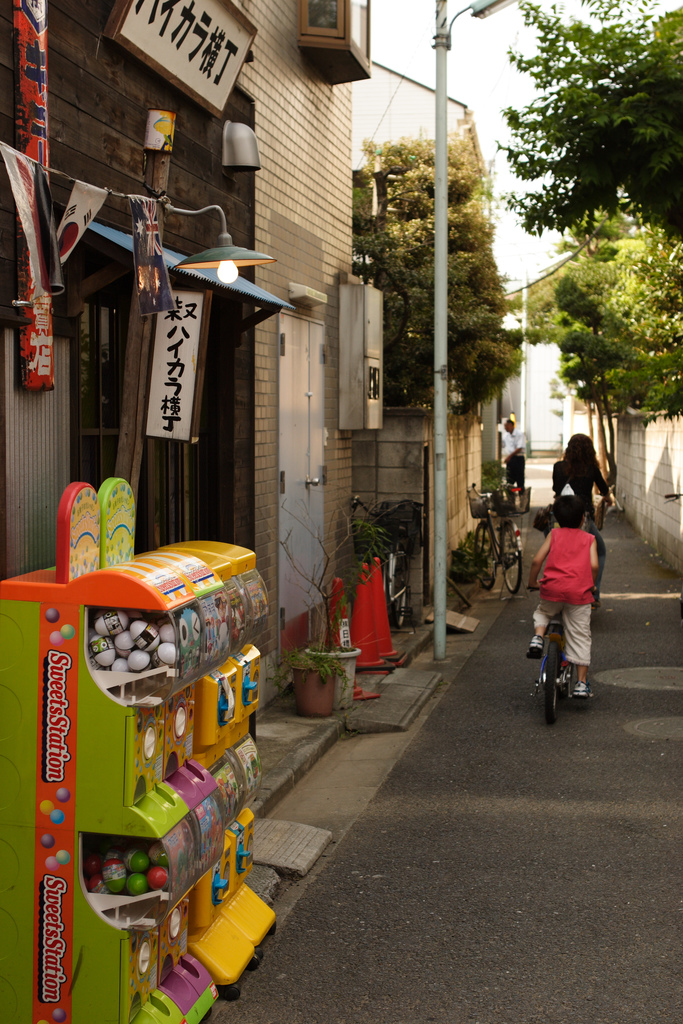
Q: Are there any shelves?
A: No, there are no shelves.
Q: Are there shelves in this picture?
A: No, there are no shelves.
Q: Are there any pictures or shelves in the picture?
A: No, there are no shelves or pictures.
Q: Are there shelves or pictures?
A: No, there are no shelves or pictures.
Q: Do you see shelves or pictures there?
A: No, there are no shelves or pictures.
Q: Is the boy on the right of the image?
A: Yes, the boy is on the right of the image.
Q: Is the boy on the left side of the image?
A: No, the boy is on the right of the image.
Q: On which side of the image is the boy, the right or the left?
A: The boy is on the right of the image.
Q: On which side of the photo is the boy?
A: The boy is on the right of the image.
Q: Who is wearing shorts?
A: The boy is wearing shorts.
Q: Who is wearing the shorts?
A: The boy is wearing shorts.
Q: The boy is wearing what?
A: The boy is wearing shorts.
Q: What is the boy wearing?
A: The boy is wearing shorts.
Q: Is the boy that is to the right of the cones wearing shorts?
A: Yes, the boy is wearing shorts.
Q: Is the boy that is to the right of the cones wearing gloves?
A: No, the boy is wearing shorts.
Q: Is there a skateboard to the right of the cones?
A: No, there is a boy to the right of the cones.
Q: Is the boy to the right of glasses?
A: No, the boy is to the right of the cones.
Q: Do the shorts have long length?
A: Yes, the shorts are long.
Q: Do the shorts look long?
A: Yes, the shorts are long.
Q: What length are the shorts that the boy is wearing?
A: The shorts are long.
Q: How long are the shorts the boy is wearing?
A: The shorts are long.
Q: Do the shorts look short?
A: No, the shorts are long.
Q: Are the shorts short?
A: No, the shorts are long.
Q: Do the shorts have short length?
A: No, the shorts are long.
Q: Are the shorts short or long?
A: The shorts are long.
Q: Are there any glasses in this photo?
A: No, there are no glasses.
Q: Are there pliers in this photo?
A: No, there are no pliers.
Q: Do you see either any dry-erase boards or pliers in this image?
A: No, there are no pliers or dry-erase boards.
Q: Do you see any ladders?
A: No, there are no ladders.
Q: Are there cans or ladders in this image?
A: No, there are no ladders or cans.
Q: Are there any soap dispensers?
A: No, there are no soap dispensers.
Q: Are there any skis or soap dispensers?
A: No, there are no soap dispensers or skis.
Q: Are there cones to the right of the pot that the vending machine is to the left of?
A: Yes, there are cones to the right of the pot.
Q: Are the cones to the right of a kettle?
A: No, the cones are to the right of a pot.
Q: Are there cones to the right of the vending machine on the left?
A: Yes, there are cones to the right of the vending machine.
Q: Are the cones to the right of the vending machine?
A: Yes, the cones are to the right of the vending machine.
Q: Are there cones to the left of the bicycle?
A: Yes, there are cones to the left of the bicycle.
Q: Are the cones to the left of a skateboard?
A: No, the cones are to the left of the bicycle.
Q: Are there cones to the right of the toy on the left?
A: Yes, there are cones to the right of the toy.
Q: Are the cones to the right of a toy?
A: Yes, the cones are to the right of a toy.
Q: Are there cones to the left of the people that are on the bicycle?
A: Yes, there are cones to the left of the people.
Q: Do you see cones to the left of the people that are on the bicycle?
A: Yes, there are cones to the left of the people.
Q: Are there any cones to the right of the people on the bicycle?
A: No, the cones are to the left of the people.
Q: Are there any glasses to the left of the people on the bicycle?
A: No, there are cones to the left of the people.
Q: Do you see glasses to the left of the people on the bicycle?
A: No, there are cones to the left of the people.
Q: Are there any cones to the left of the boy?
A: Yes, there are cones to the left of the boy.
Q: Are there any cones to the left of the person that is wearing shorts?
A: Yes, there are cones to the left of the boy.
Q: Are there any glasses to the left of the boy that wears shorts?
A: No, there are cones to the left of the boy.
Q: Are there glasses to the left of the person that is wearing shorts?
A: No, there are cones to the left of the boy.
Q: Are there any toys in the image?
A: Yes, there is a toy.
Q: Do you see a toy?
A: Yes, there is a toy.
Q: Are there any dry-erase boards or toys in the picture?
A: Yes, there is a toy.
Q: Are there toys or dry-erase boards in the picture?
A: Yes, there is a toy.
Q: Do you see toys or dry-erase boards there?
A: Yes, there is a toy.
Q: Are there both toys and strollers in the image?
A: No, there is a toy but no strollers.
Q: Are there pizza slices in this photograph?
A: No, there are no pizza slices.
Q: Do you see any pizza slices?
A: No, there are no pizza slices.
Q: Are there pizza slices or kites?
A: No, there are no pizza slices or kites.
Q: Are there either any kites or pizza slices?
A: No, there are no pizza slices or kites.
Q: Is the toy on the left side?
A: Yes, the toy is on the left of the image.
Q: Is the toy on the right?
A: No, the toy is on the left of the image.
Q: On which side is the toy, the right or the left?
A: The toy is on the left of the image.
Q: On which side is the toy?
A: The toy is on the left of the image.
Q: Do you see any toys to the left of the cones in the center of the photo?
A: Yes, there is a toy to the left of the cones.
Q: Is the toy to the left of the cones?
A: Yes, the toy is to the left of the cones.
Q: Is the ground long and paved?
A: Yes, the ground is long and paved.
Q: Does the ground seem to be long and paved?
A: Yes, the ground is long and paved.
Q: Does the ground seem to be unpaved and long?
A: No, the ground is long but paved.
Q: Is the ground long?
A: Yes, the ground is long.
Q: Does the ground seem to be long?
A: Yes, the ground is long.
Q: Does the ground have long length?
A: Yes, the ground is long.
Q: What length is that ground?
A: The ground is long.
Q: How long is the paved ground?
A: The ground is long.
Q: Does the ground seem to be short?
A: No, the ground is long.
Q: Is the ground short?
A: No, the ground is long.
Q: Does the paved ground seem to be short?
A: No, the ground is long.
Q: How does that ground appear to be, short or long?
A: The ground is long.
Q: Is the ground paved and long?
A: Yes, the ground is paved and long.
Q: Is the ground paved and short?
A: No, the ground is paved but long.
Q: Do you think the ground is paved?
A: Yes, the ground is paved.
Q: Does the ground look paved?
A: Yes, the ground is paved.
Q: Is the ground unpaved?
A: No, the ground is paved.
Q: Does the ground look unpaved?
A: No, the ground is paved.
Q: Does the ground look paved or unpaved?
A: The ground is paved.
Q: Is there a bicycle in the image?
A: Yes, there is a bicycle.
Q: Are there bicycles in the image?
A: Yes, there is a bicycle.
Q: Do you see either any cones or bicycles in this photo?
A: Yes, there is a bicycle.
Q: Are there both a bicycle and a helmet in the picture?
A: No, there is a bicycle but no helmets.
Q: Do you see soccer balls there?
A: No, there are no soccer balls.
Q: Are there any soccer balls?
A: No, there are no soccer balls.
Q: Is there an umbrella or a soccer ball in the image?
A: No, there are no soccer balls or umbrellas.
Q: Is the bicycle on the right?
A: Yes, the bicycle is on the right of the image.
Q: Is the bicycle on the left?
A: No, the bicycle is on the right of the image.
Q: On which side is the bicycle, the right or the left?
A: The bicycle is on the right of the image.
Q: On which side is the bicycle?
A: The bicycle is on the right of the image.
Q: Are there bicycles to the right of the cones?
A: Yes, there is a bicycle to the right of the cones.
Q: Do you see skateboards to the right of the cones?
A: No, there is a bicycle to the right of the cones.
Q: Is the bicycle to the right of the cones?
A: Yes, the bicycle is to the right of the cones.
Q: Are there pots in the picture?
A: Yes, there is a pot.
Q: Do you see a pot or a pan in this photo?
A: Yes, there is a pot.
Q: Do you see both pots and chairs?
A: No, there is a pot but no chairs.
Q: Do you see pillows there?
A: No, there are no pillows.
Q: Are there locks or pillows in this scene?
A: No, there are no pillows or locks.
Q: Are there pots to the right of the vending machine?
A: Yes, there is a pot to the right of the vending machine.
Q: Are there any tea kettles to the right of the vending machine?
A: No, there is a pot to the right of the vending machine.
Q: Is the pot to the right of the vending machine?
A: Yes, the pot is to the right of the vending machine.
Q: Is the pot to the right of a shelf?
A: No, the pot is to the right of the vending machine.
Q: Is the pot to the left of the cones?
A: Yes, the pot is to the left of the cones.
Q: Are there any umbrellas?
A: No, there are no umbrellas.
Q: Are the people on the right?
A: Yes, the people are on the right of the image.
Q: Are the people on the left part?
A: No, the people are on the right of the image.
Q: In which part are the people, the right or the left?
A: The people are on the right of the image.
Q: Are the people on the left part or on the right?
A: The people are on the right of the image.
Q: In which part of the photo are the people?
A: The people are on the right of the image.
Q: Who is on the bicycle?
A: The people are on the bicycle.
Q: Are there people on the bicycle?
A: Yes, there are people on the bicycle.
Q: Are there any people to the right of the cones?
A: Yes, there are people to the right of the cones.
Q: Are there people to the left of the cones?
A: No, the people are to the right of the cones.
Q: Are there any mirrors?
A: No, there are no mirrors.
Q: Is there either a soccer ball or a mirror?
A: No, there are no mirrors or soccer balls.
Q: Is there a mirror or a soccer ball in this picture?
A: No, there are no mirrors or soccer balls.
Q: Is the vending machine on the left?
A: Yes, the vending machine is on the left of the image.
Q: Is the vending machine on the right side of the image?
A: No, the vending machine is on the left of the image.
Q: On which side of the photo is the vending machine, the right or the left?
A: The vending machine is on the left of the image.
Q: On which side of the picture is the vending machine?
A: The vending machine is on the left of the image.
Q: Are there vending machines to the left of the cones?
A: Yes, there is a vending machine to the left of the cones.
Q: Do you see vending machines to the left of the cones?
A: Yes, there is a vending machine to the left of the cones.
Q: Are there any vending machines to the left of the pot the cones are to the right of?
A: Yes, there is a vending machine to the left of the pot.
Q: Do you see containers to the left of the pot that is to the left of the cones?
A: No, there is a vending machine to the left of the pot.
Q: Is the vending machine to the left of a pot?
A: Yes, the vending machine is to the left of a pot.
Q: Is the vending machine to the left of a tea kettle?
A: No, the vending machine is to the left of a pot.